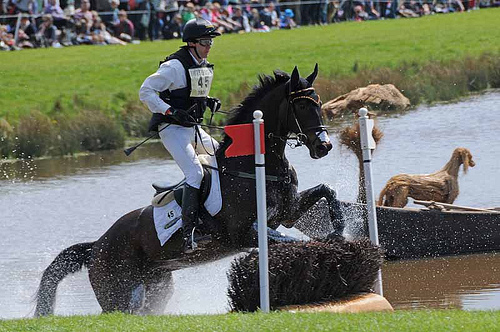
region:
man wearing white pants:
[158, 123, 228, 190]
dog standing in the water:
[379, 123, 481, 223]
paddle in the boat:
[407, 191, 495, 239]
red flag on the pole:
[224, 118, 275, 158]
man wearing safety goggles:
[192, 36, 222, 51]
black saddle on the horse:
[125, 153, 213, 194]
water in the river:
[449, 109, 489, 139]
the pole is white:
[256, 219, 276, 303]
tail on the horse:
[34, 283, 59, 309]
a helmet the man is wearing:
[187, 18, 218, 37]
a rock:
[356, 85, 398, 105]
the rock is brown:
[343, 88, 398, 105]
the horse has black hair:
[253, 79, 270, 97]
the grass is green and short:
[39, 45, 87, 85]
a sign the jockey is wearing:
[188, 69, 218, 98]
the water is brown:
[430, 268, 480, 298]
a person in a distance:
[17, 28, 34, 64]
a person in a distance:
[39, 14, 63, 33]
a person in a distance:
[71, 19, 100, 41]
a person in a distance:
[83, 18, 114, 43]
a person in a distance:
[113, 13, 143, 50]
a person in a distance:
[5, 28, 30, 72]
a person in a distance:
[233, 15, 267, 25]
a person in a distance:
[226, 15, 248, 27]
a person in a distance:
[248, 9, 270, 46]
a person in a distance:
[347, 3, 360, 24]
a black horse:
[28, 60, 341, 314]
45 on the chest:
[192, 69, 210, 92]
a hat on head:
[177, 10, 223, 37]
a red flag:
[223, 114, 267, 161]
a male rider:
[133, 10, 220, 251]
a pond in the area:
[3, 92, 499, 312]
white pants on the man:
[156, 119, 226, 255]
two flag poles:
[246, 98, 386, 312]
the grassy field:
[1, 10, 497, 134]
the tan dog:
[372, 143, 477, 206]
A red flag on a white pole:
[222, 123, 264, 155]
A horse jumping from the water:
[27, 63, 325, 313]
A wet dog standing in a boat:
[390, 148, 474, 197]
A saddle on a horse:
[148, 159, 208, 203]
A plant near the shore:
[220, 239, 388, 303]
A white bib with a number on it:
[185, 65, 212, 96]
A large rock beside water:
[324, 80, 406, 111]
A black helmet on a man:
[177, 16, 218, 37]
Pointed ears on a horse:
[284, 60, 321, 79]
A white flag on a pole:
[368, 118, 375, 150]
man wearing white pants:
[153, 121, 225, 191]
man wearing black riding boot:
[180, 183, 203, 260]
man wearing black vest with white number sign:
[138, 50, 226, 130]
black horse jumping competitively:
[32, 61, 344, 328]